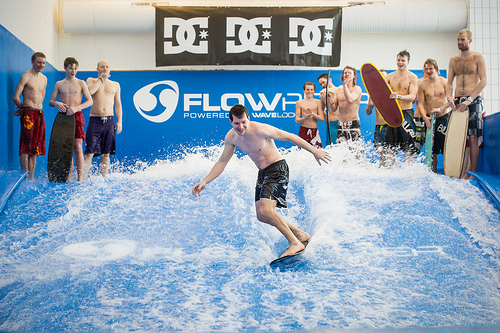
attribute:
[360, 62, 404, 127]
surfboard — red, yellow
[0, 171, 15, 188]
tarp — blue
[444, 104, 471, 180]
surfboard — tan, brown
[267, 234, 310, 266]
surfboard — small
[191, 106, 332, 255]
man — surfing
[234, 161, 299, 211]
trunks — black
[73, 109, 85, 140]
shorts — red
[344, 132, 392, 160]
water — splashing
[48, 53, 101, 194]
man — young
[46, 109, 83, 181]
surfboard — small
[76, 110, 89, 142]
shorts — red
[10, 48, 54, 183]
man — young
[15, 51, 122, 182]
guys — watching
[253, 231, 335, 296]
surfboard — small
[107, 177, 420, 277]
wave ramp — indoor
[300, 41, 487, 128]
guys — specting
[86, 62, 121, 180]
man — young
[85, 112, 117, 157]
shorts — blue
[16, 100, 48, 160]
shorts — red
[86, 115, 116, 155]
trunks — blue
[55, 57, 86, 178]
man — young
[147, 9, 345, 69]
banner — black, white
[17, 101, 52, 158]
short — red